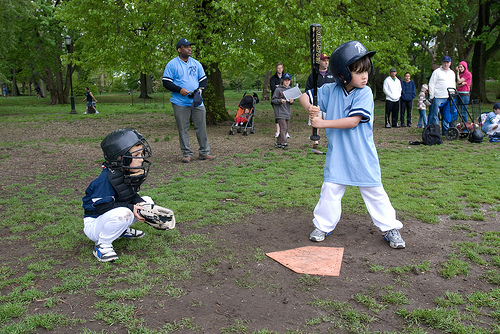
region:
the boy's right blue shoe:
[91, 241, 120, 265]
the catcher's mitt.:
[134, 197, 177, 232]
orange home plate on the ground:
[263, 243, 345, 276]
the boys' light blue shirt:
[304, 72, 384, 197]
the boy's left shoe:
[383, 227, 406, 247]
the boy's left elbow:
[348, 119, 362, 130]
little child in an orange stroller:
[229, 90, 259, 135]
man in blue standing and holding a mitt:
[161, 37, 223, 169]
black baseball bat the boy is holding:
[301, 23, 324, 149]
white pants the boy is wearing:
[311, 172, 404, 234]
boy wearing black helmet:
[305, 36, 402, 97]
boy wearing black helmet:
[65, 121, 165, 191]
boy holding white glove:
[132, 178, 200, 240]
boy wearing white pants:
[58, 192, 153, 252]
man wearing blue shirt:
[146, 22, 228, 164]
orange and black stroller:
[221, 75, 272, 153]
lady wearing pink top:
[438, 50, 482, 135]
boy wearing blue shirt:
[301, 60, 408, 219]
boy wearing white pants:
[290, 152, 435, 247]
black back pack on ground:
[412, 109, 450, 159]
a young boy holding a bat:
[296, 26, 376, 230]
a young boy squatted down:
[81, 115, 176, 273]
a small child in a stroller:
[222, 89, 263, 149]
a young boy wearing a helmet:
[319, 34, 379, 107]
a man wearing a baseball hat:
[176, 34, 197, 60]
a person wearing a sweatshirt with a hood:
[454, 58, 475, 96]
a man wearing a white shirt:
[431, 58, 456, 100]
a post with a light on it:
[55, 28, 75, 120]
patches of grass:
[200, 150, 307, 277]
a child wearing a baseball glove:
[96, 182, 211, 257]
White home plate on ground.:
[262, 242, 346, 277]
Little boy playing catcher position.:
[80, 117, 177, 262]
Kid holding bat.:
[308, 17, 405, 248]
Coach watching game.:
[158, 37, 216, 164]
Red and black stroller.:
[225, 85, 260, 136]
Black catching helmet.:
[96, 129, 153, 177]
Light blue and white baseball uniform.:
[298, 84, 410, 250]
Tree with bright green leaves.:
[41, 0, 413, 129]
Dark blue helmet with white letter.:
[328, 41, 378, 84]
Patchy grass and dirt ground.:
[408, 148, 495, 321]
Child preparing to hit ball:
[298, 22, 405, 257]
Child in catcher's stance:
[79, 124, 179, 266]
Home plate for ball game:
[264, 242, 347, 279]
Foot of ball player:
[383, 227, 407, 250]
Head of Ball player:
[328, 37, 378, 89]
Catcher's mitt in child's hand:
[135, 202, 180, 233]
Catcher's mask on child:
[99, 132, 153, 184]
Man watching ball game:
[161, 36, 216, 163]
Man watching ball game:
[381, 65, 404, 129]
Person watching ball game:
[400, 70, 413, 130]